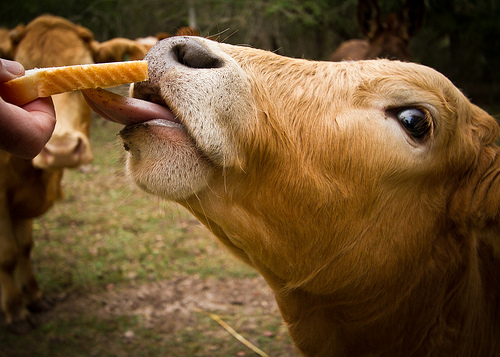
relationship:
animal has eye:
[82, 32, 500, 357] [381, 97, 446, 156]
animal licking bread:
[82, 32, 500, 357] [4, 59, 167, 97]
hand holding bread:
[0, 56, 59, 163] [4, 59, 167, 97]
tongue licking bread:
[68, 88, 167, 130] [4, 59, 167, 97]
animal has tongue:
[82, 32, 500, 357] [68, 88, 167, 130]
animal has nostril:
[82, 32, 500, 357] [170, 34, 237, 70]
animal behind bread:
[0, 13, 145, 337] [4, 59, 167, 97]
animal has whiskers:
[82, 32, 500, 357] [173, 113, 238, 218]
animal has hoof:
[0, 13, 145, 337] [3, 310, 39, 337]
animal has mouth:
[82, 32, 500, 357] [132, 69, 230, 186]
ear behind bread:
[92, 35, 149, 57] [4, 59, 167, 97]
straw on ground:
[206, 308, 263, 355] [80, 272, 257, 355]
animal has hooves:
[0, 13, 145, 337] [7, 286, 75, 350]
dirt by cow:
[42, 265, 279, 335] [82, 30, 489, 352]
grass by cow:
[0, 117, 305, 355] [82, 30, 489, 352]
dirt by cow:
[42, 265, 279, 335] [0, 11, 157, 224]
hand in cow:
[2, 51, 60, 182] [124, 33, 498, 353]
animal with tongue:
[82, 32, 500, 357] [68, 88, 167, 130]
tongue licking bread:
[68, 88, 167, 130] [6, 56, 149, 101]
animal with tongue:
[82, 32, 496, 353] [76, 83, 175, 129]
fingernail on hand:
[2, 57, 24, 77] [0, 54, 61, 156]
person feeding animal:
[0, 31, 104, 160] [82, 32, 496, 353]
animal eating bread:
[82, 32, 496, 353] [6, 34, 170, 106]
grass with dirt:
[3, 117, 288, 349] [42, 265, 279, 335]